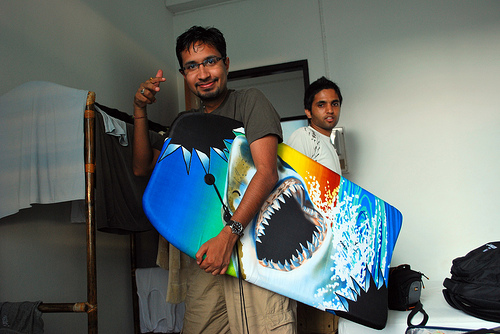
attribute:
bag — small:
[381, 262, 431, 324]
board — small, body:
[146, 96, 443, 317]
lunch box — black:
[387, 262, 428, 327]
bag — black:
[442, 237, 499, 322]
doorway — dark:
[226, 57, 308, 114]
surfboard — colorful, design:
[141, 116, 418, 326]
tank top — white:
[135, 266, 177, 332]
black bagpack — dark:
[441, 237, 498, 325]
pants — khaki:
[180, 256, 295, 332]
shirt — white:
[288, 127, 348, 174]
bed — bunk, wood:
[24, 66, 152, 244]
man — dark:
[152, 22, 244, 239]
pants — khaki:
[184, 243, 299, 332]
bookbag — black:
[440, 239, 498, 321]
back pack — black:
[440, 232, 499, 319]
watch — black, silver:
[233, 182, 297, 269]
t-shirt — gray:
[177, 85, 282, 140]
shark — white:
[247, 173, 324, 292]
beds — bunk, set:
[21, 86, 181, 310]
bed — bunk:
[13, 42, 168, 224]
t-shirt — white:
[133, 90, 315, 217]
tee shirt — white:
[279, 117, 348, 177]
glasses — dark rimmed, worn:
[172, 52, 268, 89]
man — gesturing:
[132, 29, 314, 331]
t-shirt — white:
[286, 122, 345, 176]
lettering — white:
[484, 245, 485, 252]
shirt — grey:
[192, 81, 284, 148]